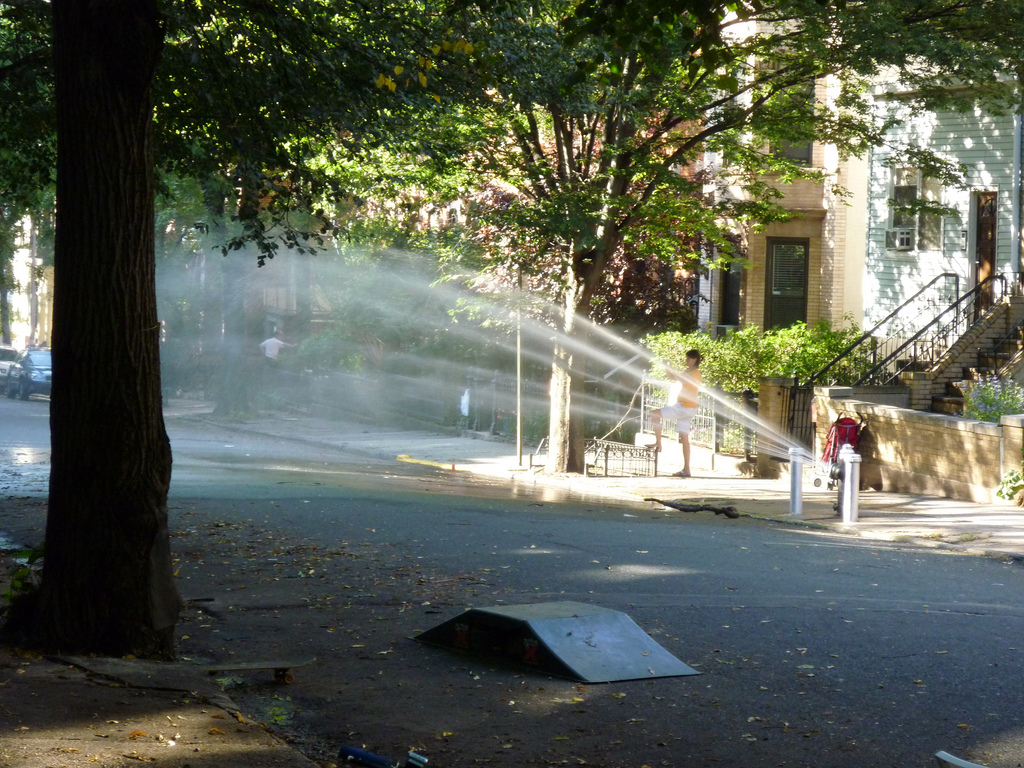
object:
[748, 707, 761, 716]
leaf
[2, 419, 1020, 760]
ground.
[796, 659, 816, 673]
leaf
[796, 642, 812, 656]
leaf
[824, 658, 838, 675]
leaf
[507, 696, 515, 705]
leaf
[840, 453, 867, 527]
post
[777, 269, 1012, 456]
stairs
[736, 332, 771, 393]
shrubbery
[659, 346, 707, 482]
person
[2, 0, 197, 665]
tree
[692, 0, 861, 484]
building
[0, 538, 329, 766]
sidewalk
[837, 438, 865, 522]
hydrant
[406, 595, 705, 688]
ramp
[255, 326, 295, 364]
man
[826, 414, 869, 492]
carriage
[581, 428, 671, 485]
bench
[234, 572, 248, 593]
leafs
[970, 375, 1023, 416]
flowers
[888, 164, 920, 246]
window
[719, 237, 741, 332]
window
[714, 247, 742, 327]
window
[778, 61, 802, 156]
window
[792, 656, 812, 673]
leaf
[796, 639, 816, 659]
leaf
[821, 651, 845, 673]
leaf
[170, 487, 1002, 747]
ground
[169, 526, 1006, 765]
ground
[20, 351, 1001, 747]
street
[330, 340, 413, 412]
water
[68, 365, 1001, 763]
road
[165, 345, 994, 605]
sidewalk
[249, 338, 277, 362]
shirt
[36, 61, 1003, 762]
outside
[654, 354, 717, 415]
shirt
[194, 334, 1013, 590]
sidewalk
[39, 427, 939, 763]
ground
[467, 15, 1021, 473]
house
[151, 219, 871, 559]
water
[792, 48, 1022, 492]
building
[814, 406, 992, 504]
wall